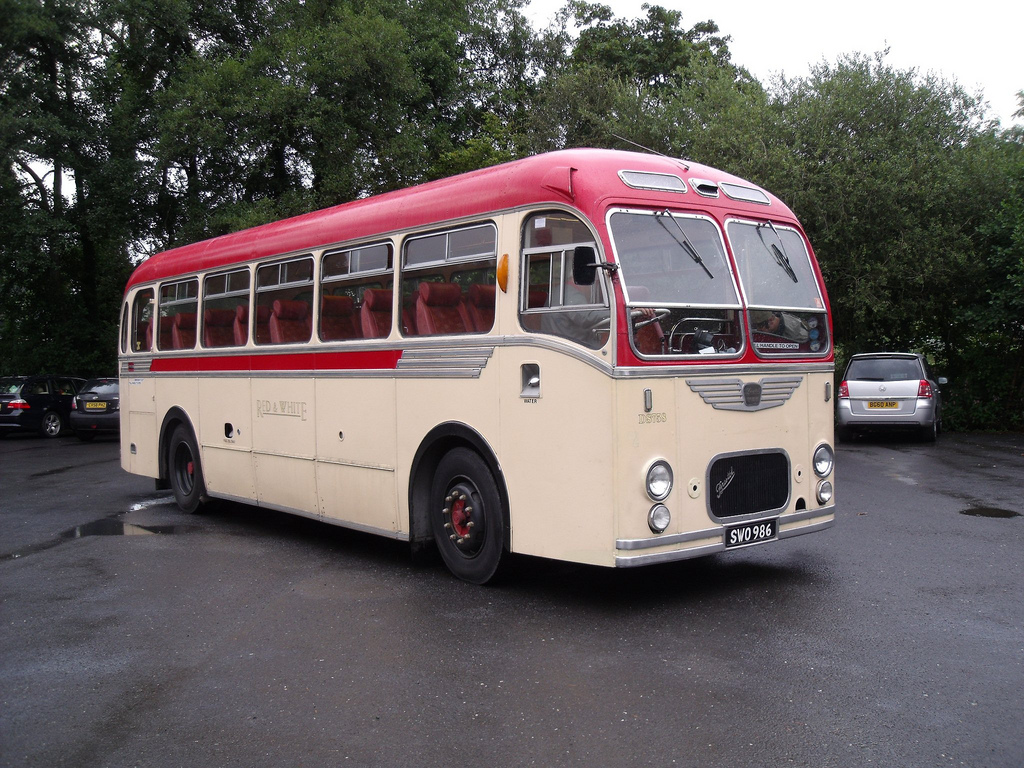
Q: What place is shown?
A: It is a road.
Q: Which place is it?
A: It is a road.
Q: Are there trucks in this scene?
A: No, there are no trucks.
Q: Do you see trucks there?
A: No, there are no trucks.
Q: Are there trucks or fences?
A: No, there are no trucks or fences.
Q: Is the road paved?
A: Yes, the road is paved.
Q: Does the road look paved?
A: Yes, the road is paved.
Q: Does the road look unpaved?
A: No, the road is paved.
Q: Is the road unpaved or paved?
A: The road is paved.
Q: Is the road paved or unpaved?
A: The road is paved.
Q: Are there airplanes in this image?
A: No, there are no airplanes.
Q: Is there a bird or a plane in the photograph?
A: No, there are no airplanes or birds.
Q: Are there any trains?
A: No, there are no trains.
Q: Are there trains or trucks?
A: No, there are no trains or trucks.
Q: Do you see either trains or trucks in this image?
A: No, there are no trains or trucks.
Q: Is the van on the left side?
A: Yes, the van is on the left of the image.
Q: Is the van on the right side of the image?
A: No, the van is on the left of the image.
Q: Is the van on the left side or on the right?
A: The van is on the left of the image.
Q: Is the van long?
A: Yes, the van is long.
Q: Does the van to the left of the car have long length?
A: Yes, the van is long.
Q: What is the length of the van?
A: The van is long.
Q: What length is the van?
A: The van is long.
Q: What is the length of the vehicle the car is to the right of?
A: The van is long.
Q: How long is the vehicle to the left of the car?
A: The van is long.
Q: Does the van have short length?
A: No, the van is long.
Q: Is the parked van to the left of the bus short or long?
A: The van is long.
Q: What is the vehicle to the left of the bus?
A: The vehicle is a van.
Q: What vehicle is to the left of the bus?
A: The vehicle is a van.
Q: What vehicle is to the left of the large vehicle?
A: The vehicle is a van.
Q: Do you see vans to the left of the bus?
A: Yes, there is a van to the left of the bus.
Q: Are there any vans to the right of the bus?
A: No, the van is to the left of the bus.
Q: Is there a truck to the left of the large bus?
A: No, there is a van to the left of the bus.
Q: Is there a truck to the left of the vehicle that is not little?
A: No, there is a van to the left of the bus.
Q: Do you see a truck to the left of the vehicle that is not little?
A: No, there is a van to the left of the bus.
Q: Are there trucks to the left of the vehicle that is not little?
A: No, there is a van to the left of the bus.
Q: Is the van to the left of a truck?
A: No, the van is to the left of the bus.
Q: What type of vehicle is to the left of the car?
A: The vehicle is a van.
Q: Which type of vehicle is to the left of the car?
A: The vehicle is a van.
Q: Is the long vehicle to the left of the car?
A: Yes, the van is to the left of the car.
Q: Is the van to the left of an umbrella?
A: No, the van is to the left of the car.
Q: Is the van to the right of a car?
A: No, the van is to the left of a car.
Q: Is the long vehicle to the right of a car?
A: No, the van is to the left of a car.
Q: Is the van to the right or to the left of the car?
A: The van is to the left of the car.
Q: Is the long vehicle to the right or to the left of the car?
A: The van is to the left of the car.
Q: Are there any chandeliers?
A: No, there are no chandeliers.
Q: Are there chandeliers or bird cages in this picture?
A: No, there are no chandeliers or bird cages.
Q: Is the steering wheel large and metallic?
A: Yes, the steering wheel is large and metallic.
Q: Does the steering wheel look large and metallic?
A: Yes, the steering wheel is large and metallic.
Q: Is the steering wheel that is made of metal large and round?
A: Yes, the steering wheel is large and round.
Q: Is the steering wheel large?
A: Yes, the steering wheel is large.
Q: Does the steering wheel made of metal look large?
A: Yes, the steering wheel is large.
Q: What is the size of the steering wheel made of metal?
A: The steering wheel is large.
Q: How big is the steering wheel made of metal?
A: The steering wheel is large.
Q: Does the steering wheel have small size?
A: No, the steering wheel is large.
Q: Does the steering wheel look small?
A: No, the steering wheel is large.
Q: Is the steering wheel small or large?
A: The steering wheel is large.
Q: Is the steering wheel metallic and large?
A: Yes, the steering wheel is metallic and large.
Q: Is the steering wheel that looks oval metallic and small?
A: No, the steering wheel is metallic but large.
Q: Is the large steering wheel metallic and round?
A: Yes, the steering wheel is metallic and round.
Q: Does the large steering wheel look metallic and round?
A: Yes, the steering wheel is metallic and round.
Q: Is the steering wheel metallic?
A: Yes, the steering wheel is metallic.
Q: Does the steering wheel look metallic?
A: Yes, the steering wheel is metallic.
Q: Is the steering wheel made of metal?
A: Yes, the steering wheel is made of metal.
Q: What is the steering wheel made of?
A: The steering wheel is made of metal.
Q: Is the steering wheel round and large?
A: Yes, the steering wheel is round and large.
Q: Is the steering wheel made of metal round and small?
A: No, the steering wheel is round but large.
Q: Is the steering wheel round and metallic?
A: Yes, the steering wheel is round and metallic.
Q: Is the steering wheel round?
A: Yes, the steering wheel is round.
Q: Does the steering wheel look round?
A: Yes, the steering wheel is round.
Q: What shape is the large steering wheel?
A: The steering wheel is round.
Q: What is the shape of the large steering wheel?
A: The steering wheel is round.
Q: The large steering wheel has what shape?
A: The steering wheel is round.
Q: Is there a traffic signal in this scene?
A: No, there are no traffic lights.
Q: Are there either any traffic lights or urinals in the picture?
A: No, there are no traffic lights or urinals.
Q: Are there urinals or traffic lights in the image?
A: No, there are no traffic lights or urinals.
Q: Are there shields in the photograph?
A: No, there are no shields.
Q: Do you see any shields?
A: No, there are no shields.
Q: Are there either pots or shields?
A: No, there are no shields or pots.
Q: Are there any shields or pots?
A: No, there are no shields or pots.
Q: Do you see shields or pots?
A: No, there are no shields or pots.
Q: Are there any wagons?
A: No, there are no wagons.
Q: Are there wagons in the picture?
A: No, there are no wagons.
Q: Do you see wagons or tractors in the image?
A: No, there are no wagons or tractors.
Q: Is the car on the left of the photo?
A: Yes, the car is on the left of the image.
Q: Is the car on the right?
A: No, the car is on the left of the image.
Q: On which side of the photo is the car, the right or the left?
A: The car is on the left of the image.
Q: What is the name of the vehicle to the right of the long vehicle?
A: The vehicle is a car.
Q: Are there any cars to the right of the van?
A: Yes, there is a car to the right of the van.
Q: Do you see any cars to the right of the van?
A: Yes, there is a car to the right of the van.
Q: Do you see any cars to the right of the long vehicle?
A: Yes, there is a car to the right of the van.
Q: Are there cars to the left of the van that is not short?
A: No, the car is to the right of the van.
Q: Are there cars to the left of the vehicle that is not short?
A: No, the car is to the right of the van.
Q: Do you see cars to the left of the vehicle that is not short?
A: No, the car is to the right of the van.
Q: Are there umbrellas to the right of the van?
A: No, there is a car to the right of the van.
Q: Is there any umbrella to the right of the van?
A: No, there is a car to the right of the van.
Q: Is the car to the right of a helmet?
A: No, the car is to the right of a van.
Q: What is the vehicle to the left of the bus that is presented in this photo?
A: The vehicle is a car.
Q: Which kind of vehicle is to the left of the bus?
A: The vehicle is a car.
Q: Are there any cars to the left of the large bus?
A: Yes, there is a car to the left of the bus.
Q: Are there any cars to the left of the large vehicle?
A: Yes, there is a car to the left of the bus.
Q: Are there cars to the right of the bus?
A: No, the car is to the left of the bus.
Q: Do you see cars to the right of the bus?
A: No, the car is to the left of the bus.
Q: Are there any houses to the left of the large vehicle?
A: No, there is a car to the left of the bus.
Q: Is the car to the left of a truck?
A: No, the car is to the left of a bus.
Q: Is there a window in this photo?
A: Yes, there is a window.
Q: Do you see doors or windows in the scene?
A: Yes, there is a window.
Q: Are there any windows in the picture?
A: Yes, there is a window.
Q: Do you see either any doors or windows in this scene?
A: Yes, there is a window.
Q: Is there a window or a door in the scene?
A: Yes, there is a window.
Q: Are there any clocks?
A: No, there are no clocks.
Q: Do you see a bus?
A: Yes, there is a bus.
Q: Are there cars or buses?
A: Yes, there is a bus.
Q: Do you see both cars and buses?
A: Yes, there are both a bus and a car.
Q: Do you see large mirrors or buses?
A: Yes, there is a large bus.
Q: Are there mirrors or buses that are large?
A: Yes, the bus is large.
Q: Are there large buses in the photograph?
A: Yes, there is a large bus.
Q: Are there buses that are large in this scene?
A: Yes, there is a large bus.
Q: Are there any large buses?
A: Yes, there is a large bus.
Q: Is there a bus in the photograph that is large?
A: Yes, there is a bus that is large.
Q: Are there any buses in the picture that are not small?
A: Yes, there is a large bus.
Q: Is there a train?
A: No, there are no trains.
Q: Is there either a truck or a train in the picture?
A: No, there are no trains or trucks.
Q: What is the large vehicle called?
A: The vehicle is a bus.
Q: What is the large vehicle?
A: The vehicle is a bus.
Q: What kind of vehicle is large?
A: The vehicle is a bus.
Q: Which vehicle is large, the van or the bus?
A: The bus is large.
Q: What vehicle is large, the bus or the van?
A: The bus is large.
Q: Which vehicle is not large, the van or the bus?
A: The van is not large.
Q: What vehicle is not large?
A: The vehicle is a van.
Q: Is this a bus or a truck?
A: This is a bus.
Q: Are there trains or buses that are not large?
A: No, there is a bus but it is large.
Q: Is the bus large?
A: Yes, the bus is large.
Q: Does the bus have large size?
A: Yes, the bus is large.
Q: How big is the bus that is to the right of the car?
A: The bus is large.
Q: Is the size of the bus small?
A: No, the bus is large.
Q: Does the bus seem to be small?
A: No, the bus is large.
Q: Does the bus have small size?
A: No, the bus is large.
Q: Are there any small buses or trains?
A: No, there is a bus but it is large.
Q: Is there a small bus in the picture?
A: No, there is a bus but it is large.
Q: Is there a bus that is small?
A: No, there is a bus but it is large.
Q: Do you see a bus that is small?
A: No, there is a bus but it is large.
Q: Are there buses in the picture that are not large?
A: No, there is a bus but it is large.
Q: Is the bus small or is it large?
A: The bus is large.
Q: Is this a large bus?
A: Yes, this is a large bus.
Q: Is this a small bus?
A: No, this is a large bus.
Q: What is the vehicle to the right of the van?
A: The vehicle is a bus.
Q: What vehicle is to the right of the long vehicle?
A: The vehicle is a bus.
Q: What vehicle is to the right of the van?
A: The vehicle is a bus.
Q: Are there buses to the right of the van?
A: Yes, there is a bus to the right of the van.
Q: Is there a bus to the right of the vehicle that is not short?
A: Yes, there is a bus to the right of the van.